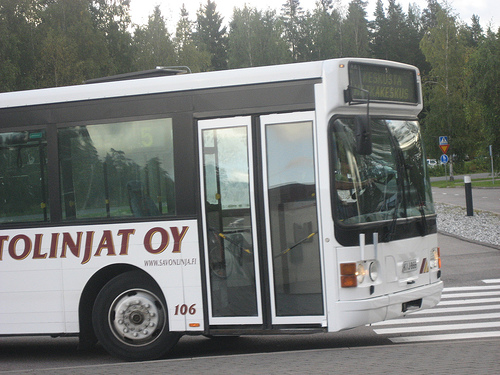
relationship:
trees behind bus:
[126, 0, 178, 75] [2, 45, 452, 365]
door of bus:
[194, 110, 327, 334] [2, 45, 452, 365]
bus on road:
[2, 45, 452, 365] [1, 315, 497, 372]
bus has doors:
[2, 45, 452, 365] [192, 109, 324, 336]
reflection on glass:
[83, 130, 175, 199] [56, 116, 178, 221]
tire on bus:
[86, 268, 185, 363] [2, 45, 452, 365]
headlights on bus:
[339, 258, 378, 288] [2, 45, 452, 365]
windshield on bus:
[327, 112, 434, 225] [2, 45, 452, 365]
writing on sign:
[353, 69, 408, 86] [346, 57, 418, 103]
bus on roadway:
[2, 45, 452, 365] [5, 316, 498, 370]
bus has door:
[2, 45, 452, 365] [186, 102, 330, 334]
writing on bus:
[2, 224, 188, 267] [2, 45, 452, 365]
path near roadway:
[436, 176, 495, 276] [366, 249, 491, 374]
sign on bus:
[53, 51, 487, 366] [2, 45, 452, 365]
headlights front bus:
[340, 246, 443, 288] [2, 45, 452, 365]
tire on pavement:
[86, 268, 185, 363] [3, 352, 498, 374]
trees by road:
[5, 2, 498, 59] [432, 187, 497, 214]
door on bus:
[194, 110, 327, 334] [2, 45, 452, 365]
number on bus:
[171, 299, 199, 317] [2, 45, 452, 365]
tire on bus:
[86, 268, 185, 363] [18, 28, 394, 373]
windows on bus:
[22, 134, 290, 224] [65, 80, 499, 308]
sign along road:
[433, 134, 450, 166] [0, 170, 498, 372]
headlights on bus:
[339, 258, 378, 288] [11, 23, 435, 373]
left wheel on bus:
[89, 270, 179, 360] [2, 45, 452, 365]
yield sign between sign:
[436, 143, 449, 155] [434, 133, 449, 149]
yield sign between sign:
[436, 143, 449, 155] [436, 152, 453, 168]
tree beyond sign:
[365, 0, 437, 82] [438, 137, 446, 145]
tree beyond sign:
[365, 0, 437, 82] [437, 154, 449, 166]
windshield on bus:
[327, 112, 435, 225] [10, 72, 423, 331]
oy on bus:
[141, 219, 191, 257] [2, 45, 452, 365]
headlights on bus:
[351, 256, 382, 283] [2, 45, 452, 365]